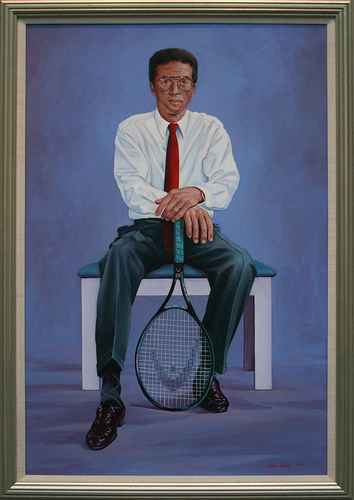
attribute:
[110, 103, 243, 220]
shirt — white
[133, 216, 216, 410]
racquet — tennis racquet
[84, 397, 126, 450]
shoe — dark brown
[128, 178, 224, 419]
racket — green 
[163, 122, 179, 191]
tie — red 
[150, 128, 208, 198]
tie — red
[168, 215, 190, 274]
handle — blue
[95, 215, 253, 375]
pants — blue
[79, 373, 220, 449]
shoes — dress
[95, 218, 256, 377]
slacks — green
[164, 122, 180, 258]
tie — red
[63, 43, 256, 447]
portrait — a man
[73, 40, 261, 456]
man — sitting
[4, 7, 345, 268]
painting — oil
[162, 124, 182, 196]
tie — deep red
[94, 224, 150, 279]
pants — green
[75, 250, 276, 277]
cushion — blue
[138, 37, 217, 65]
hair — dark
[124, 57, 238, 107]
glasses — large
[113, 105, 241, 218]
white shirt — button up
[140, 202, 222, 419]
racket — tennis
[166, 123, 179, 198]
tie — burgundy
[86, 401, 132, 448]
shoes — burgundy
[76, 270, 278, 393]
bench — white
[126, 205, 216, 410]
racket — blue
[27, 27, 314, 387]
background — blue